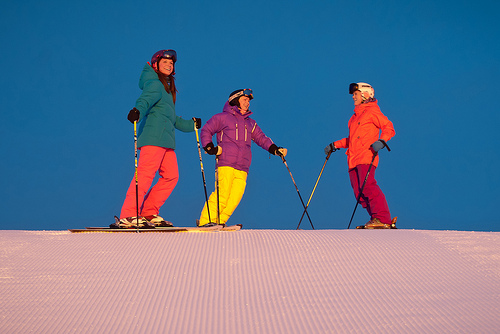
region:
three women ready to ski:
[62, 50, 404, 332]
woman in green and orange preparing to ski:
[99, 25, 198, 242]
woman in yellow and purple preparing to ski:
[191, 57, 310, 273]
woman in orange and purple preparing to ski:
[306, 65, 429, 242]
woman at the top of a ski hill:
[56, 33, 456, 324]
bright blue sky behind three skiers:
[40, 15, 460, 260]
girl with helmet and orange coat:
[319, 63, 414, 138]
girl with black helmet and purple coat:
[203, 68, 283, 177]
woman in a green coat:
[96, 34, 206, 164]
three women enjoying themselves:
[16, 13, 469, 248]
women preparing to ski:
[99, 34, 424, 245]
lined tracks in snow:
[169, 234, 343, 311]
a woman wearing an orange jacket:
[339, 71, 403, 228]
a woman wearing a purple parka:
[207, 86, 253, 226]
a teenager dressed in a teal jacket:
[100, 34, 187, 242]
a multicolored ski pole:
[184, 120, 211, 228]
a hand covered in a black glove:
[124, 110, 146, 127]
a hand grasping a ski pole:
[270, 142, 292, 165]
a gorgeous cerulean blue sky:
[256, 18, 421, 83]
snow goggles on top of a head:
[228, 89, 265, 94]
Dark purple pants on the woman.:
[345, 161, 395, 223]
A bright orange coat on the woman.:
[325, 103, 396, 168]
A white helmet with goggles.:
[343, 74, 387, 99]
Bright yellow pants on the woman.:
[198, 159, 251, 227]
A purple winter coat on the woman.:
[196, 99, 290, 174]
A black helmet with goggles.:
[216, 86, 261, 116]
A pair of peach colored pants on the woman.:
[98, 132, 184, 231]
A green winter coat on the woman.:
[121, 68, 197, 155]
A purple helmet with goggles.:
[141, 41, 183, 73]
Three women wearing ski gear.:
[56, 41, 435, 271]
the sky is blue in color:
[8, 58, 474, 223]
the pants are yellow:
[203, 168, 248, 220]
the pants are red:
[121, 155, 188, 212]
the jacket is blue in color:
[121, 83, 192, 149]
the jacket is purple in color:
[208, 107, 275, 168]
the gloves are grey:
[363, 133, 391, 158]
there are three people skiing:
[86, 50, 396, 250]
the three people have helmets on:
[120, 56, 388, 219]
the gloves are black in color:
[198, 141, 285, 157]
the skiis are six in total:
[132, 56, 399, 222]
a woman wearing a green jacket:
[119, 37, 189, 152]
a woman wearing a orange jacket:
[333, 77, 384, 184]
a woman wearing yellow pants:
[191, 72, 268, 227]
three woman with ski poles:
[40, 38, 411, 238]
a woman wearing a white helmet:
[337, 70, 382, 119]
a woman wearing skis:
[75, 51, 182, 250]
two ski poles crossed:
[251, 134, 344, 229]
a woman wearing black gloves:
[119, 46, 209, 130]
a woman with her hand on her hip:
[192, 87, 256, 173]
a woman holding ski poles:
[98, 30, 210, 237]